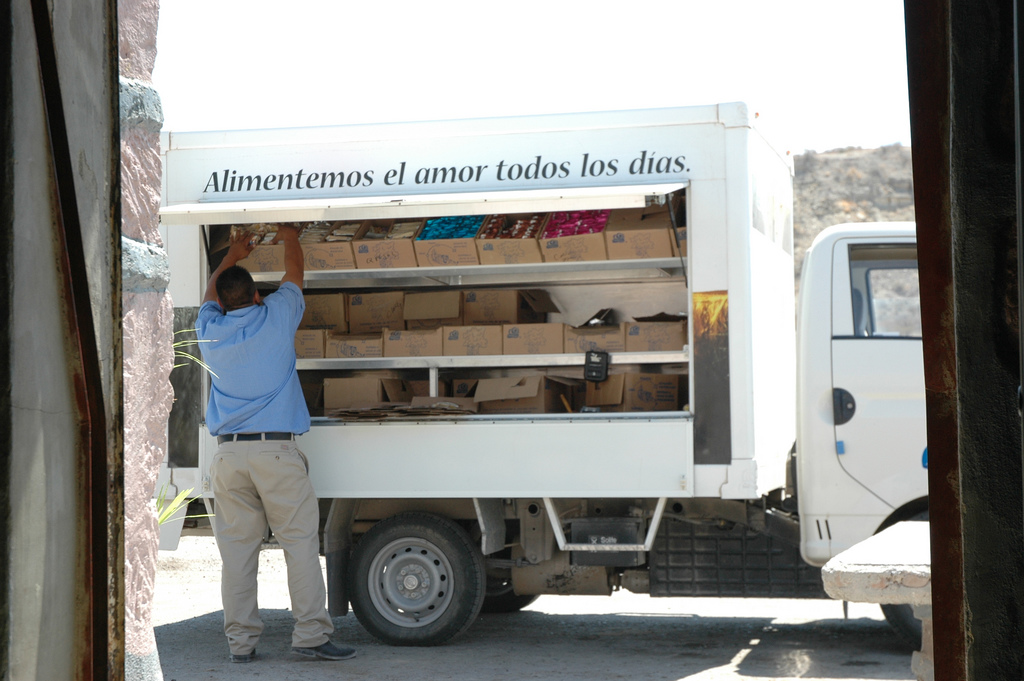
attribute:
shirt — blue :
[181, 302, 314, 435]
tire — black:
[354, 508, 484, 664]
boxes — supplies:
[305, 231, 689, 274]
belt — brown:
[217, 424, 294, 444]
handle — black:
[823, 389, 856, 429]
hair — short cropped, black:
[193, 236, 361, 673]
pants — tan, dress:
[209, 434, 331, 644]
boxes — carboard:
[233, 225, 687, 413]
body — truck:
[164, 82, 806, 521]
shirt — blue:
[183, 288, 324, 472]